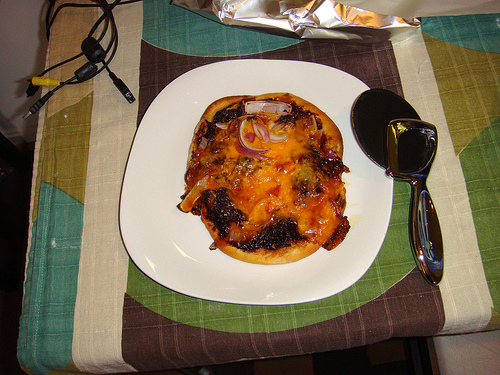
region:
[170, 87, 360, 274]
individual pizza, with caviar or burnt spinach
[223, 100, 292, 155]
some sliced red onion on the individual pizza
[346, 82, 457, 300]
a pizza cutter w/ a brown handle that looks sorta kinda like a hairbrush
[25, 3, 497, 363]
a barkcloth tablecloth turned under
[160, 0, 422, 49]
some slightly crumply thick aluminium foil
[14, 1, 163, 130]
several cables, an audio cable yellowheaded but to what?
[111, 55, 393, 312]
plate is square w/ rounded edges, individual pizza is fairly similarly shaped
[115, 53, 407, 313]
plate is white, pizza is mostly orange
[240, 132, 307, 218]
an orange cheese over a red tomato sauce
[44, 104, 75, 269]
two white spots at the edge of the barkcloth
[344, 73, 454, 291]
a pizza cutter next to a plate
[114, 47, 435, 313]
a round edged square plate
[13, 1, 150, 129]
cords on a tablecloth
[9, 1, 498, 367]
a green, blue, white and brown tablecloth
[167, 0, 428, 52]
tin foil laying on a tablecloth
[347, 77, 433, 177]
the round cutting wheel of a pizza cutter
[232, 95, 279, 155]
red onion pieces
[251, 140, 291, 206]
bright yellow cheese on a pizza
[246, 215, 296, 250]
a burnt spot on a pizza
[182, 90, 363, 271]
a small roundish pizza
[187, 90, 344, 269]
food on white plate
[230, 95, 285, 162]
purple onion slices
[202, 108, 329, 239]
melted cheese on crust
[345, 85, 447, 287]
pizza cutter on table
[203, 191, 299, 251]
burnt cheese on pizza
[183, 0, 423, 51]
foil on table cloth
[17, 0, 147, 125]
charge cords on table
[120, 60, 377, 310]
white plate on table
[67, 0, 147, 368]
stripe on table cloth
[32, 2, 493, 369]
table cloth on table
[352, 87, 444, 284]
the shiny pizza cutter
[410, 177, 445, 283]
the silver handle of pizza cutter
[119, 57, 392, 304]
the white plate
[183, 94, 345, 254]
the small pizza on the white plate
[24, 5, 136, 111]
the wires on the table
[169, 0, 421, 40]
the foil on the table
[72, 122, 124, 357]
the thick white stripe on the table cloth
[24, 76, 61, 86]
the yellow plastic piece of the wire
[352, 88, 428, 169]
the circle piece of the pizza cutter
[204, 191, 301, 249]
the burnt parts on top of the pizza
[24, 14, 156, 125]
a whole lot of wires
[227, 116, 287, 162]
onions on the food on the plate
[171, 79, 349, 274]
homemade food on a white plate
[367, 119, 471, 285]
a spoon next to the plate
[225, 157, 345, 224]
melted cheese on the food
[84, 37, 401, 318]
a white plate containing food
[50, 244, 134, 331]
tablecloth that the plate is resting on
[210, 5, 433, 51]
tin foil sitting on the table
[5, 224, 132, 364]
corner of the table with the tablecloth on it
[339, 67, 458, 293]
pizza cutter next to the plate